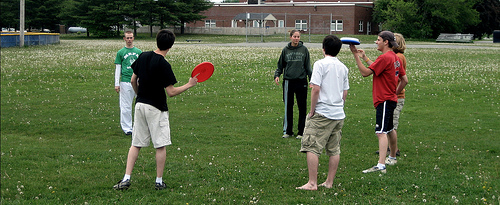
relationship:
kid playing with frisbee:
[113, 28, 142, 134] [338, 33, 361, 45]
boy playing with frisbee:
[111, 29, 206, 190] [338, 33, 361, 45]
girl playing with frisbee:
[272, 30, 312, 138] [338, 33, 361, 45]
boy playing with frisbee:
[294, 35, 351, 191] [192, 61, 215, 81]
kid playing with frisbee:
[395, 33, 404, 153] [192, 61, 215, 81]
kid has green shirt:
[113, 28, 142, 134] [114, 45, 140, 82]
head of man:
[323, 35, 341, 57] [298, 34, 351, 197]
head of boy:
[157, 27, 174, 54] [111, 29, 206, 190]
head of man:
[121, 29, 133, 44] [114, 30, 140, 134]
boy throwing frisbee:
[140, 13, 192, 138] [191, 59, 215, 85]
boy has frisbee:
[350, 31, 391, 176] [341, 31, 361, 49]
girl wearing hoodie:
[271, 28, 313, 138] [261, 44, 315, 79]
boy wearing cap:
[349, 31, 409, 173] [379, 24, 395, 47]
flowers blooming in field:
[25, 34, 498, 81] [412, 52, 489, 182]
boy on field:
[288, 33, 353, 194] [4, 37, 497, 204]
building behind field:
[182, 2, 375, 33] [4, 37, 497, 204]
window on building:
[330, 19, 344, 31] [185, 0, 376, 37]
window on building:
[291, 20, 308, 31] [185, 0, 376, 37]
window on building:
[203, 17, 218, 30] [185, 0, 376, 37]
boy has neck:
[111, 29, 206, 190] [156, 46, 169, 54]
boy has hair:
[111, 29, 206, 190] [153, 26, 178, 50]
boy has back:
[111, 29, 206, 190] [135, 48, 171, 105]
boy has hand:
[111, 29, 206, 190] [188, 54, 217, 86]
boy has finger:
[111, 29, 206, 190] [193, 74, 198, 77]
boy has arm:
[111, 29, 206, 190] [161, 64, 192, 95]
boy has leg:
[111, 29, 206, 190] [151, 111, 164, 193]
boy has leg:
[111, 29, 206, 190] [113, 110, 138, 192]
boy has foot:
[111, 29, 206, 190] [108, 175, 133, 192]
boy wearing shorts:
[111, 29, 206, 190] [129, 97, 174, 151]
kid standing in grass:
[113, 28, 142, 134] [4, 26, 498, 203]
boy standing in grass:
[111, 29, 206, 190] [4, 26, 498, 203]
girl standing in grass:
[272, 30, 312, 138] [4, 26, 498, 203]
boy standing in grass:
[294, 35, 351, 191] [4, 26, 498, 203]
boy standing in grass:
[349, 31, 409, 173] [4, 26, 498, 203]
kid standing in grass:
[374, 33, 405, 157] [4, 26, 498, 203]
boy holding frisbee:
[111, 29, 206, 190] [189, 61, 216, 82]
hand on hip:
[306, 109, 315, 119] [302, 98, 347, 122]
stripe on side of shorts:
[378, 99, 386, 134] [373, 102, 398, 137]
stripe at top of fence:
[3, 28, 53, 37] [1, 37, 62, 46]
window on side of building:
[330, 16, 344, 36] [182, 2, 375, 33]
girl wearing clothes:
[272, 30, 312, 138] [287, 44, 304, 136]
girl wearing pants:
[272, 30, 312, 138] [278, 78, 312, 135]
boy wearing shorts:
[294, 35, 351, 191] [280, 99, 373, 163]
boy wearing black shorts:
[349, 31, 409, 173] [371, 97, 406, 136]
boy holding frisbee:
[111, 29, 206, 190] [187, 58, 217, 86]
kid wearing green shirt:
[113, 28, 142, 134] [114, 46, 142, 81]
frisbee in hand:
[186, 58, 223, 96] [184, 76, 196, 91]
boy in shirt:
[111, 29, 206, 190] [107, 47, 184, 109]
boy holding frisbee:
[111, 29, 206, 190] [192, 59, 216, 76]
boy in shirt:
[294, 35, 351, 191] [318, 58, 345, 113]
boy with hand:
[294, 35, 351, 191] [306, 109, 314, 119]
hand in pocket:
[306, 109, 314, 119] [303, 120, 318, 132]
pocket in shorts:
[303, 120, 318, 132] [287, 102, 344, 156]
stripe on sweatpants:
[282, 80, 292, 137] [277, 73, 315, 142]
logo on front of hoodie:
[271, 50, 312, 67] [277, 42, 309, 85]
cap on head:
[374, 26, 401, 46] [374, 36, 391, 59]